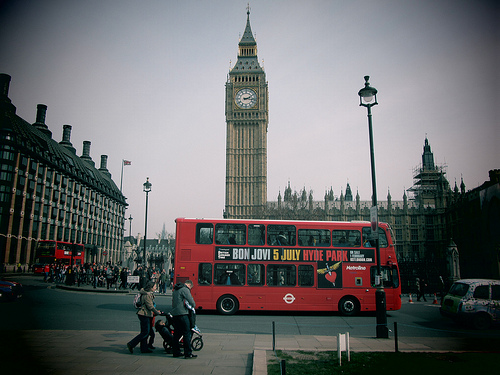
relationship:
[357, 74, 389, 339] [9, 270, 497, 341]
street lamp above street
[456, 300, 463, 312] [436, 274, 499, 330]
light on a car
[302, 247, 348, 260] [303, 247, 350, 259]
hyde park in lettering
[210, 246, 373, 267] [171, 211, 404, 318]
poster on bus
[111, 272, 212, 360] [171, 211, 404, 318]
people look at bus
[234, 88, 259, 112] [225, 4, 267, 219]
face on tower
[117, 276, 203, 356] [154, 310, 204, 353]
people pushing stroller